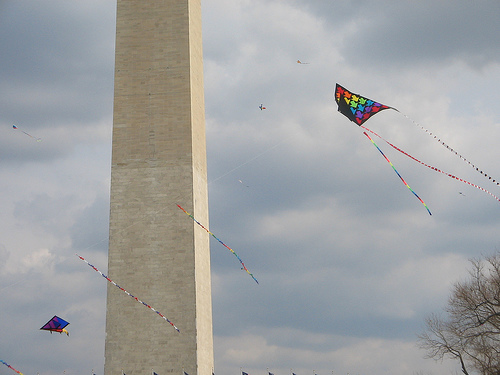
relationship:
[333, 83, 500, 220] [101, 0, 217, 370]
kite next to a building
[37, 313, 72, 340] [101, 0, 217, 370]
kite next to a building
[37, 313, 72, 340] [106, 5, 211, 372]
kite next to a building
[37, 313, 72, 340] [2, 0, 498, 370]
kite in sky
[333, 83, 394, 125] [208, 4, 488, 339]
kite in sky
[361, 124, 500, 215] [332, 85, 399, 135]
kite tail on kite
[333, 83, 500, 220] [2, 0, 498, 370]
kite in sky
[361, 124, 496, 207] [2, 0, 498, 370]
kite tail in sky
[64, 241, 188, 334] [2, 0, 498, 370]
kite tail in sky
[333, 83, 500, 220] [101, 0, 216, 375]
kite flown over building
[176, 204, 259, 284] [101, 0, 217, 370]
kite next to building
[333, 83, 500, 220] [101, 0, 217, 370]
kite next to building